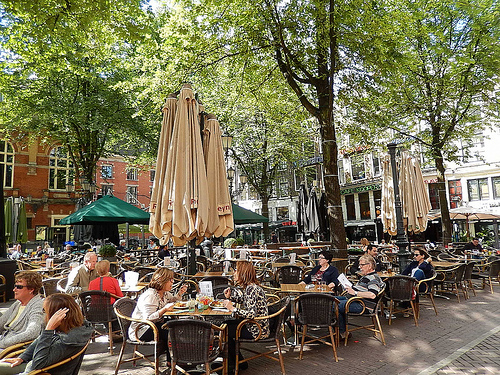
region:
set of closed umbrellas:
[161, 83, 233, 238]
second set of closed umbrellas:
[383, 150, 430, 233]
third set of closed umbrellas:
[7, 195, 29, 245]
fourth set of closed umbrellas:
[298, 179, 327, 241]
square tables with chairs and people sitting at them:
[63, 251, 398, 351]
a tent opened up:
[62, 192, 152, 224]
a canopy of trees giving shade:
[6, 0, 499, 88]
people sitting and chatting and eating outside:
[126, 263, 286, 361]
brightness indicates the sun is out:
[103, 5, 243, 83]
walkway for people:
[356, 326, 498, 373]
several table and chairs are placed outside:
[16, 215, 494, 364]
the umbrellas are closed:
[146, 80, 434, 266]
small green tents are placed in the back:
[59, 185, 269, 233]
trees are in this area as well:
[16, 3, 484, 155]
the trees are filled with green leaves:
[13, 5, 493, 153]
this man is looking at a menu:
[333, 255, 391, 305]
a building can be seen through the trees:
[246, 92, 499, 217]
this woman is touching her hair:
[37, 291, 85, 332]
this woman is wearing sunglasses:
[11, 275, 31, 295]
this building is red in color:
[3, 87, 213, 244]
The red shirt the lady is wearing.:
[89, 275, 116, 300]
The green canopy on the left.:
[67, 193, 153, 232]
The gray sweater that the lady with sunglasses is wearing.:
[2, 296, 39, 339]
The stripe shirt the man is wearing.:
[353, 270, 378, 300]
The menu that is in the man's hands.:
[338, 273, 350, 289]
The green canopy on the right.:
[226, 201, 274, 225]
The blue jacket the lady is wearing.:
[307, 263, 337, 282]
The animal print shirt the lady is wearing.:
[231, 282, 267, 338]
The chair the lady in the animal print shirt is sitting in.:
[242, 283, 292, 370]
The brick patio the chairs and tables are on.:
[304, 270, 499, 373]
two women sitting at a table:
[137, 261, 268, 360]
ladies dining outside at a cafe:
[133, 255, 269, 350]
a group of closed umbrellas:
[154, 73, 229, 254]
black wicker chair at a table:
[159, 321, 224, 374]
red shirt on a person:
[91, 271, 121, 308]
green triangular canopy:
[64, 178, 152, 238]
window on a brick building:
[49, 137, 77, 196]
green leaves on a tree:
[118, 38, 138, 80]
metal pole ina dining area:
[386, 135, 410, 282]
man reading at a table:
[331, 248, 386, 330]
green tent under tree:
[59, 193, 149, 247]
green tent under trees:
[232, 202, 268, 241]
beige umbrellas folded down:
[149, 80, 235, 251]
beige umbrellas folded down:
[376, 154, 431, 236]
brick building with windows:
[0, 95, 158, 250]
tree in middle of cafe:
[2, 0, 162, 233]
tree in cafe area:
[342, 1, 499, 246]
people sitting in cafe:
[0, 233, 493, 372]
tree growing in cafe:
[186, 0, 419, 270]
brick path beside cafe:
[419, 327, 497, 374]